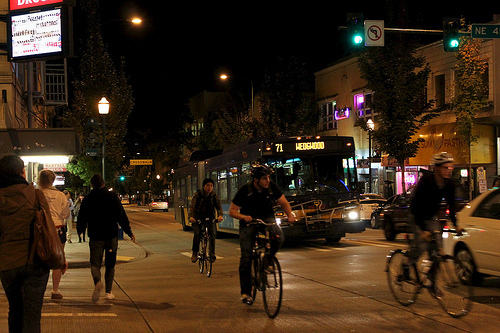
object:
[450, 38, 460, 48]
green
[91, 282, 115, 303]
shoes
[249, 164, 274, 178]
helmet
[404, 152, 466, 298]
man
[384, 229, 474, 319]
bike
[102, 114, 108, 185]
lamp post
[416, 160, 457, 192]
ground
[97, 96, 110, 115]
street light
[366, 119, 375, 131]
street light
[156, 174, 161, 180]
street light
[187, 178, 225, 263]
man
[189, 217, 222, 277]
bike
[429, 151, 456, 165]
helmet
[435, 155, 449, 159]
silver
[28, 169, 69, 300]
athlete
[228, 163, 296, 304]
man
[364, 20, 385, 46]
sign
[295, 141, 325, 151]
sign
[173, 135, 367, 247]
bus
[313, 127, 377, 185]
ground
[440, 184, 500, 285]
car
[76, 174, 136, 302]
people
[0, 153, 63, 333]
people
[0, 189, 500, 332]
street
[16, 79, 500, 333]
scene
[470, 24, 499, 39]
street sign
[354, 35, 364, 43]
light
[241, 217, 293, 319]
bicylce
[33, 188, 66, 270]
bag